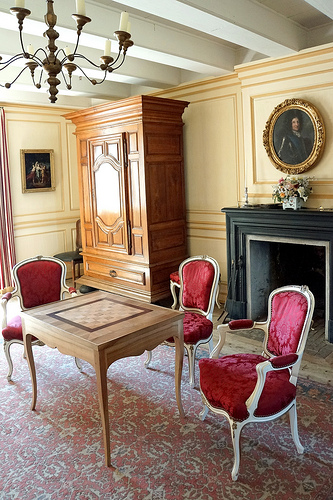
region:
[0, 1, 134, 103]
brown brass chandelier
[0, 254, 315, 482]
red and white chairs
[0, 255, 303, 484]
red white and velvet chairs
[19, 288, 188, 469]
brown checkers table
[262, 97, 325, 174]
gold frame picture of man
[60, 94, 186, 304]
brown wood cabinet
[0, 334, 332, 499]
white and red carpet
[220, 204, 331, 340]
old black fireplace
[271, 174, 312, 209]
light colored flowers in white pot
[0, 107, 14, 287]
red and white long curtain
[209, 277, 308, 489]
chair near a table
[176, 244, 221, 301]
chair near a table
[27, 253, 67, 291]
chair near a table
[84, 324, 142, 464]
table in a room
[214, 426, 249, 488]
leg on a chair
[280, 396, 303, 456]
leg of a chair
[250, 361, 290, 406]
arm of a chair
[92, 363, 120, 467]
leg of a table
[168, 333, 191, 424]
leg of a table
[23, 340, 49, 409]
leg of a table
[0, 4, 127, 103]
The candles on the chandelier.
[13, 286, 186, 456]
The wooden table in the center.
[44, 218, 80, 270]
The chair in the corner.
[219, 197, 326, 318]
The fireplace against the wall.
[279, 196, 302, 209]
The flower vase on the shelf of the fireplace.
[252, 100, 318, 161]
The circle frame above the fireplace.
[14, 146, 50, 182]
The square frame hanging on the wall.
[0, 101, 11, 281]
The red and white curtains on the window.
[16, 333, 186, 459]
The legs of the table.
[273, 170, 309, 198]
The flowers in the vase on the shelf above the fireplace.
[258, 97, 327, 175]
round painting of man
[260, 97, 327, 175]
oval painting in gold frame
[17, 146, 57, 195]
rectangular painting in gold frame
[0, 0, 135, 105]
metal chandler with white candles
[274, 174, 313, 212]
flowers in white square box on mantle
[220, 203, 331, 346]
fireplace with black mantle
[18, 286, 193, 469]
square wooden table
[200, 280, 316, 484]
white chair with red cushions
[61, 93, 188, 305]
large tall wooden wardrobe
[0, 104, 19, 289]
red and white stripped curtains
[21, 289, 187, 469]
a gaming table with curved legs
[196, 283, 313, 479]
a cushioned chair in antique style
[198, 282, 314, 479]
a queen Anne chair with cushions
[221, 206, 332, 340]
a dark and simple fireplace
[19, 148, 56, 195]
a piece of art appropriate for the design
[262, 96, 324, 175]
a person from generations ago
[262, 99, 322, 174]
reproduction of a painting of a European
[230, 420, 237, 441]
a little gold leaf on the chair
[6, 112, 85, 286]
a wall with much gold trim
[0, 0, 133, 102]
a light fixture that appears to have candles